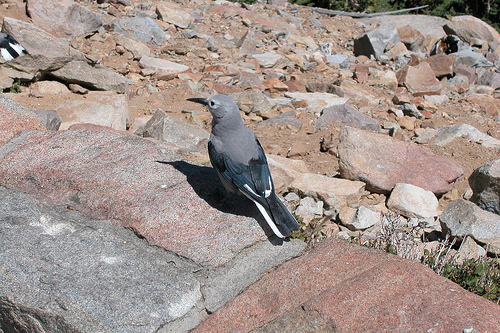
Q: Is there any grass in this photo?
A: Yes, there is grass.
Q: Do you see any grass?
A: Yes, there is grass.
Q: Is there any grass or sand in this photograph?
A: Yes, there is grass.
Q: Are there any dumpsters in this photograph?
A: No, there are no dumpsters.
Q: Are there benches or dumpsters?
A: No, there are no dumpsters or benches.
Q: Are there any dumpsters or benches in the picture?
A: No, there are no dumpsters or benches.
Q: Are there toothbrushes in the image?
A: No, there are no toothbrushes.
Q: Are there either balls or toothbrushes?
A: No, there are no toothbrushes or balls.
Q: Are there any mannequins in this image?
A: No, there are no mannequins.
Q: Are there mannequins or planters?
A: No, there are no mannequins or planters.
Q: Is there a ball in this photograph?
A: No, there are no balls.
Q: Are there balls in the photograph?
A: No, there are no balls.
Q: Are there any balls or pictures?
A: No, there are no balls or pictures.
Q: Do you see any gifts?
A: No, there are no gifts.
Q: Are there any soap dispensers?
A: No, there are no soap dispensers.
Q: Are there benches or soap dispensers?
A: No, there are no soap dispensers or benches.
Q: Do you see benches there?
A: No, there are no benches.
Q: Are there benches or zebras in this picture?
A: No, there are no benches or zebras.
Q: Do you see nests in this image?
A: No, there are no nests.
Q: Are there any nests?
A: No, there are no nests.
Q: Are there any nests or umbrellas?
A: No, there are no nests or umbrellas.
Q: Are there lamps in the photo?
A: No, there are no lamps.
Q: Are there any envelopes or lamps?
A: No, there are no lamps or envelopes.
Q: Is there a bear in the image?
A: No, there are no bears.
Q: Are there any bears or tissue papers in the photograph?
A: No, there are no bears or tissue papers.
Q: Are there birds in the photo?
A: Yes, there is a bird.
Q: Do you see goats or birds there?
A: Yes, there is a bird.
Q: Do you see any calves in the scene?
A: No, there are no calves.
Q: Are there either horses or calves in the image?
A: No, there are no calves or horses.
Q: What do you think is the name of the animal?
A: The animal is a bird.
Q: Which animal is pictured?
A: The animal is a bird.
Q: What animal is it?
A: The animal is a bird.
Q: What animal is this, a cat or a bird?
A: This is a bird.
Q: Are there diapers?
A: No, there are no diapers.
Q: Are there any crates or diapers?
A: No, there are no diapers or crates.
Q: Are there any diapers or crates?
A: No, there are no diapers or crates.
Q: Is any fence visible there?
A: No, there are no fences.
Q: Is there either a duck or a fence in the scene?
A: No, there are no fences or ducks.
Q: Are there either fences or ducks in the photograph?
A: No, there are no fences or ducks.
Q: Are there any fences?
A: No, there are no fences.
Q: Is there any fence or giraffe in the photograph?
A: No, there are no fences or giraffes.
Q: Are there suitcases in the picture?
A: No, there are no suitcases.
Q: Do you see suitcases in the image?
A: No, there are no suitcases.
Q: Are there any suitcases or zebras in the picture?
A: No, there are no suitcases or zebras.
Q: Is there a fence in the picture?
A: No, there are no fences.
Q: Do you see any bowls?
A: No, there are no bowls.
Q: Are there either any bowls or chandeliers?
A: No, there are no bowls or chandeliers.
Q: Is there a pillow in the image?
A: No, there are no pillows.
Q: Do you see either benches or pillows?
A: No, there are no pillows or benches.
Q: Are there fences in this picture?
A: No, there are no fences.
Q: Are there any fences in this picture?
A: No, there are no fences.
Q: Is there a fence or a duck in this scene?
A: No, there are no fences or ducks.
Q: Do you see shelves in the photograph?
A: No, there are no shelves.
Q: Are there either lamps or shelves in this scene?
A: No, there are no shelves or lamps.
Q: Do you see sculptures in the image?
A: No, there are no sculptures.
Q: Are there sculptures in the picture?
A: No, there are no sculptures.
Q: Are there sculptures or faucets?
A: No, there are no sculptures or faucets.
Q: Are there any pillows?
A: No, there are no pillows.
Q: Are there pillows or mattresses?
A: No, there are no pillows or mattresses.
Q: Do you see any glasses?
A: No, there are no glasses.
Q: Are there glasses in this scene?
A: No, there are no glasses.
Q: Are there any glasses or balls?
A: No, there are no glasses or balls.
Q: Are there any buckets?
A: No, there are no buckets.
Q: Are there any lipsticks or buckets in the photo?
A: No, there are no buckets or lipsticks.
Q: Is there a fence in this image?
A: No, there are no fences.